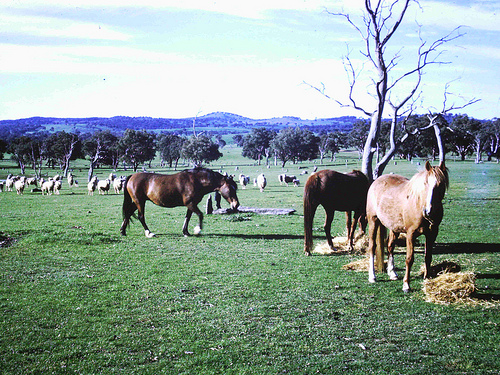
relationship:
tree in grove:
[188, 136, 220, 167] [4, 120, 499, 176]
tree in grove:
[159, 135, 186, 168] [4, 120, 499, 176]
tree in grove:
[123, 131, 155, 170] [4, 120, 499, 176]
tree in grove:
[86, 134, 122, 171] [4, 120, 499, 176]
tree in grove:
[52, 130, 80, 177] [4, 120, 499, 176]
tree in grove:
[273, 130, 298, 168] [4, 120, 499, 176]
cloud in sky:
[406, 29, 437, 38] [0, 2, 499, 122]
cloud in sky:
[0, 8, 138, 45] [0, 2, 499, 122]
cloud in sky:
[2, 42, 169, 67] [0, 2, 499, 122]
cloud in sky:
[408, 44, 500, 59] [0, 2, 499, 122]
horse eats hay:
[366, 160, 448, 293] [419, 269, 476, 303]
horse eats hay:
[303, 168, 375, 255] [419, 269, 476, 303]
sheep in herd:
[85, 177, 98, 196] [1, 172, 267, 195]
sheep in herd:
[256, 174, 267, 191] [1, 172, 267, 195]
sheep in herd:
[238, 175, 248, 188] [1, 172, 267, 195]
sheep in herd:
[110, 177, 124, 191] [1, 172, 267, 195]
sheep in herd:
[13, 176, 27, 192] [1, 172, 267, 195]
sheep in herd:
[4, 176, 16, 191] [1, 172, 267, 195]